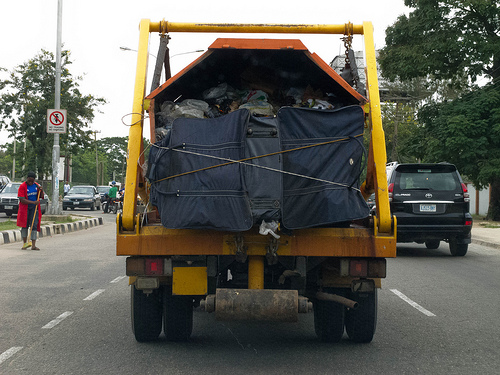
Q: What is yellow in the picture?
A: A trash truck.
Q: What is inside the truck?
A: Trash.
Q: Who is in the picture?
A: An African American woman.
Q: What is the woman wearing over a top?
A: Red coat.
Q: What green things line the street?
A: Trees.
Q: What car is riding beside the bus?
A: Black SUV.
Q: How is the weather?
A: Overcast.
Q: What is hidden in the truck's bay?
A: Garbage.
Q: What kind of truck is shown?
A: A garbage truck.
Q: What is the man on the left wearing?
A: A red coat.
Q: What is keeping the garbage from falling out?
A: A mesh wall.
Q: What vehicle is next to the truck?
A: A black SUV.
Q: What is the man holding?
A: A broom.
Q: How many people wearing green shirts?
A: 1.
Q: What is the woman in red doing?
A: Sweeping.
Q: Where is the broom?
A: In the woman's hand.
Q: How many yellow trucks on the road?
A: 1.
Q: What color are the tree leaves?
A: Green.